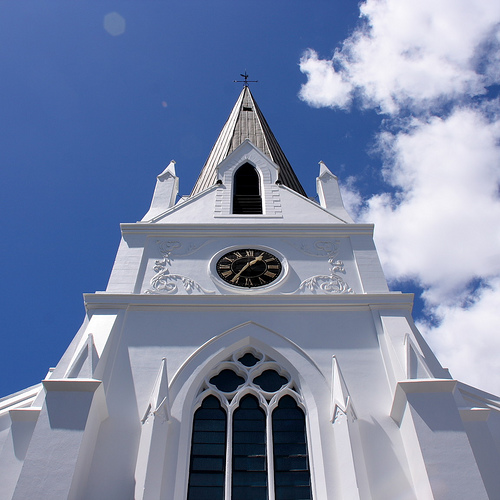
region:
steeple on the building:
[185, 57, 302, 189]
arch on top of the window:
[175, 315, 325, 405]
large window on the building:
[140, 321, 375, 496]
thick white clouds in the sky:
[286, 0, 496, 391]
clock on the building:
[200, 245, 293, 291]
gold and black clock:
[208, 243, 290, 289]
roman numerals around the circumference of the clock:
[211, 238, 289, 297]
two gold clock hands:
[231, 250, 269, 281]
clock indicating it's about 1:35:
[213, 240, 290, 290]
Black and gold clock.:
[216, 247, 284, 289]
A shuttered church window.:
[187, 345, 311, 498]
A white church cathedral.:
[0, 70, 499, 498]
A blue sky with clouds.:
[0, 0, 499, 401]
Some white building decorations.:
[287, 236, 354, 293]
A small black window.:
[231, 155, 261, 217]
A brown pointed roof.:
[186, 85, 311, 200]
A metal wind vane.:
[233, 65, 261, 85]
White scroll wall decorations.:
[141, 233, 216, 293]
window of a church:
[215, 365, 240, 395]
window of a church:
[233, 349, 261, 367]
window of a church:
[259, 369, 287, 393]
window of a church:
[197, 399, 221, 419]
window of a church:
[237, 393, 259, 414]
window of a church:
[270, 386, 310, 426]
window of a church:
[197, 426, 217, 451]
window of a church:
[277, 431, 304, 458]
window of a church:
[195, 458, 225, 482]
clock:
[194, 239, 292, 296]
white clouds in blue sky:
[340, 56, 397, 121]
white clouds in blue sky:
[428, 193, 488, 264]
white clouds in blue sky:
[392, 93, 432, 143]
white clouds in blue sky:
[315, 53, 383, 118]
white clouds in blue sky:
[384, 15, 469, 136]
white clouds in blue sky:
[348, 102, 453, 183]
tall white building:
[68, 69, 449, 499]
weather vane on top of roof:
[223, 46, 266, 98]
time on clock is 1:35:
[210, 237, 305, 295]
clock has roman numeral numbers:
[203, 232, 293, 292]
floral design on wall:
[296, 244, 363, 296]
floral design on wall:
[157, 237, 194, 294]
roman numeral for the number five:
[257, 273, 269, 286]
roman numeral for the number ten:
[218, 250, 239, 268]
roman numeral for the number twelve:
[244, 244, 256, 262]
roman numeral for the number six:
[243, 275, 258, 289]